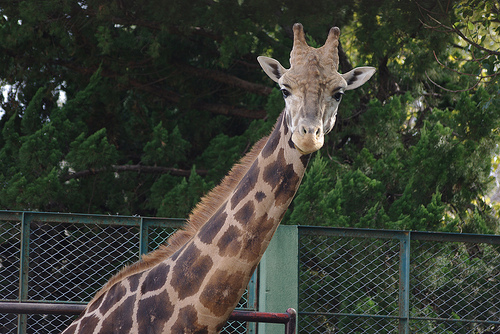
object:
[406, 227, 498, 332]
wire-meshed fance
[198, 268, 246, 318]
dot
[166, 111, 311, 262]
giraffe's neck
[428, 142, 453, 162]
ground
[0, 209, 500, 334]
fence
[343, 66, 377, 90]
ear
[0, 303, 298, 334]
red bar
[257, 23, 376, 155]
head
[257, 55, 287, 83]
ears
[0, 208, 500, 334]
green fence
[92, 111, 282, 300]
hair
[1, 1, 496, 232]
green branch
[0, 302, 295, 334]
railing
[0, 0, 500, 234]
branch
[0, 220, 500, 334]
chain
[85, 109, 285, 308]
mane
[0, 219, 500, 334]
mesh fence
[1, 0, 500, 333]
green trees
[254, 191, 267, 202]
spot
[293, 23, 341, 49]
horns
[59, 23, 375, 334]
giraffe